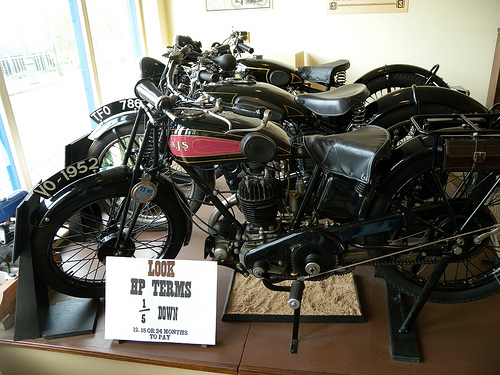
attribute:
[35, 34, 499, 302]
motorcycles — shiny, black, for sale, inside, sold, big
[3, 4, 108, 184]
window — glowing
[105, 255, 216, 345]
sign — small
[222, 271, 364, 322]
tray — black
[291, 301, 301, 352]
kickstand — black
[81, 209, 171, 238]
spoke — metal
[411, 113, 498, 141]
rack — black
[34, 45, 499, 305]
bike — black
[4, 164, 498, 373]
platform — wooden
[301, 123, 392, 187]
seats — seat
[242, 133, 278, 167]
tank — black